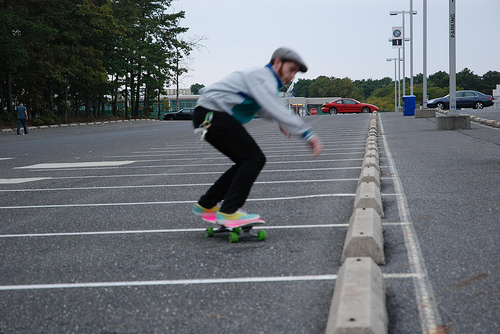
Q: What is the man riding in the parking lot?
A: The man is riding a skateboard.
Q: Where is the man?
A: In a parking lot.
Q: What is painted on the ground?
A: White lines.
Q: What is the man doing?
A: Skateboarding.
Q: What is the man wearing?
A: Black pants.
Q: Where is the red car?
A: Behind the man.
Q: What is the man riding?
A: A skateboard.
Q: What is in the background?
A: Trees.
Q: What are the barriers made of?
A: Concrete.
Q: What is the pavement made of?
A: Blacktop.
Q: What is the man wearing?
A: A sweatshirt.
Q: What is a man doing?
A: Skateboarding.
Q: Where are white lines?
A: On the ground.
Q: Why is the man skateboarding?
A: Recreation.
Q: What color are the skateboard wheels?
A: Green.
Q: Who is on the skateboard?
A: The man.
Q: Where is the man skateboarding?
A: Parking lot.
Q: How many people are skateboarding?
A: One.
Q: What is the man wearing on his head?
A: Hat.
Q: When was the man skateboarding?
A: Daytime.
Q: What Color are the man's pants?
A: Black.